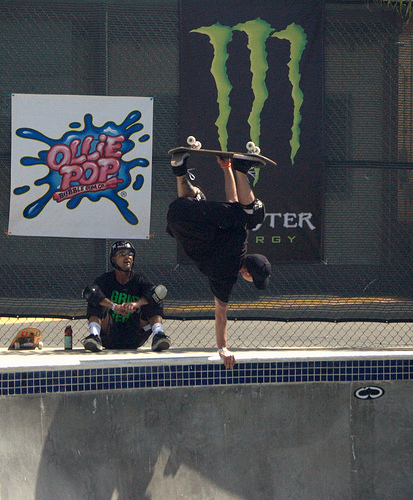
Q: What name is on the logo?
A: Monster.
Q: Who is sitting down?
A: A man.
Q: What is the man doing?
A: Skateboard tricks.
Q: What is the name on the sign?
A: Ollie pop bubble gum.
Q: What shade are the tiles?
A: Blue and white.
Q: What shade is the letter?
A: Green.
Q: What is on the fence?
A: A sign.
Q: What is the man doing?
A: Skateboarding.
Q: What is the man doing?
A: A trick.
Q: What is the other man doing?
A: Sitting.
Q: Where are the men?
A: In a skate park.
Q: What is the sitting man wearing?
A: A helmet.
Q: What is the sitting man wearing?
A: Pads.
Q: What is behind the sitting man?
A: A fence.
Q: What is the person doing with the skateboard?
A: Handstanding on one hand with feet and skateboard in the air.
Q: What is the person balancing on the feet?
A: Skateboard.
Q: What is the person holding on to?
A: Rim of skate ramp.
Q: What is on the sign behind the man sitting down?
A: Ollie pop.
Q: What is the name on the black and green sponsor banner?
A: Monster energy.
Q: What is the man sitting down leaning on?
A: Fence.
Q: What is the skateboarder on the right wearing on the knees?
A: Knee pads.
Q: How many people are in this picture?
A: Two.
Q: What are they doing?
A: Skateboarding.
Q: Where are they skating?
A: At a skateboard park.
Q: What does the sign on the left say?
A: Ollie Pop.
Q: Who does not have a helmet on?
A: The guy doing the trick.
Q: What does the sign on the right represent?
A: Monster.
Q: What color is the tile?
A: Blue and white.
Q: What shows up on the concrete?
A: Shadows.